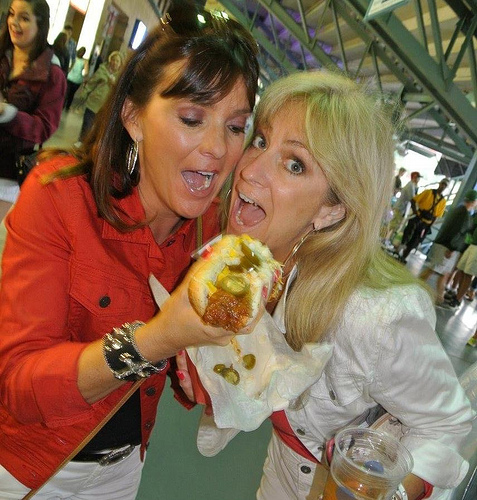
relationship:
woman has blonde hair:
[114, 49, 416, 291] [296, 59, 425, 190]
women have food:
[66, 27, 413, 309] [187, 232, 285, 333]